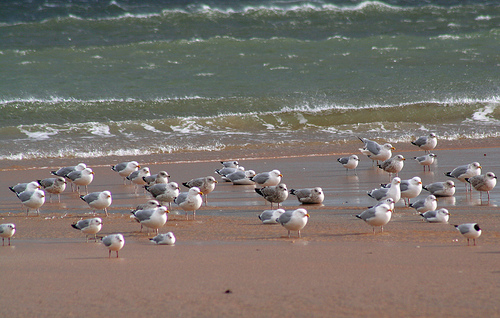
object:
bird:
[131, 200, 162, 214]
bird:
[275, 208, 310, 238]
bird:
[454, 223, 482, 247]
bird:
[71, 217, 103, 243]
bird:
[249, 169, 283, 188]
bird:
[337, 154, 361, 175]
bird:
[16, 190, 46, 217]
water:
[1, 0, 500, 243]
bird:
[258, 208, 285, 224]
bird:
[80, 190, 111, 217]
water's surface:
[0, 18, 500, 157]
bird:
[290, 187, 325, 205]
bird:
[174, 187, 204, 220]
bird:
[355, 204, 392, 234]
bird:
[411, 133, 438, 154]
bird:
[420, 208, 452, 224]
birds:
[290, 187, 325, 204]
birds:
[337, 154, 361, 175]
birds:
[112, 160, 141, 185]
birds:
[182, 175, 218, 206]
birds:
[65, 168, 95, 197]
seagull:
[222, 169, 256, 184]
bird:
[149, 232, 176, 245]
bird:
[131, 206, 171, 237]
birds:
[367, 177, 401, 211]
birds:
[255, 184, 288, 210]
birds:
[368, 198, 396, 211]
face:
[474, 224, 482, 232]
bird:
[100, 234, 125, 259]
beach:
[1, 147, 500, 314]